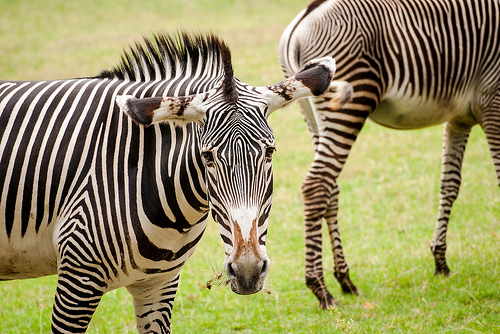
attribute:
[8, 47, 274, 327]
zebra — eyes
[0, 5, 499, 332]
grass field — green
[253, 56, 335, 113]
ear — laying half way down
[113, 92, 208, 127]
ear — laying half way down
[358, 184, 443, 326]
grass — green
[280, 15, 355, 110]
tail — zebra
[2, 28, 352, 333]
zebra's — nostrils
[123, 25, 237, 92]
mane — black, white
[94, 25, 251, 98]
zebra — spiked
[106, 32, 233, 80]
mane — black and white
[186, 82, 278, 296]
face — long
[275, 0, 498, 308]
zebra — black, white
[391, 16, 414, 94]
stripe — white, black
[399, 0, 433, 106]
stripe — white, black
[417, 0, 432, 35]
stripe — white, black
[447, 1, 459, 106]
stripe — white, black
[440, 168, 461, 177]
stripe — white, black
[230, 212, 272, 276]
nose — brown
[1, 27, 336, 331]
zebra — black, white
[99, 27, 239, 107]
mane — black